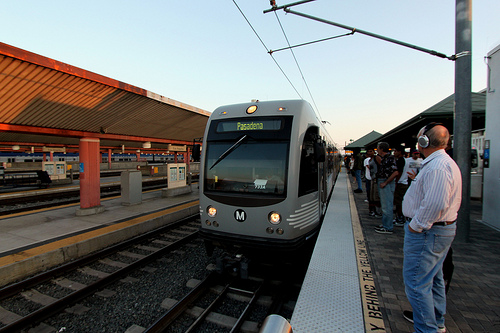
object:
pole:
[453, 0, 471, 246]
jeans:
[402, 218, 457, 333]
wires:
[225, 0, 335, 140]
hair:
[420, 124, 450, 149]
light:
[278, 107, 284, 111]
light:
[245, 104, 258, 114]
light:
[220, 111, 228, 115]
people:
[393, 144, 425, 227]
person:
[362, 153, 371, 204]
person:
[395, 149, 424, 227]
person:
[349, 154, 355, 177]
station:
[338, 40, 498, 331]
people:
[366, 148, 383, 219]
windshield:
[203, 114, 293, 209]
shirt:
[400, 149, 464, 234]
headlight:
[267, 211, 282, 226]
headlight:
[205, 204, 218, 218]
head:
[416, 123, 450, 155]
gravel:
[111, 286, 162, 318]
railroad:
[0, 223, 320, 328]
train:
[196, 98, 343, 245]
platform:
[288, 152, 498, 324]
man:
[374, 141, 399, 234]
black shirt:
[375, 152, 399, 178]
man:
[401, 122, 464, 332]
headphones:
[417, 122, 443, 148]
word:
[356, 238, 385, 331]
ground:
[0, 162, 484, 332]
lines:
[1, 197, 201, 266]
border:
[0, 199, 199, 285]